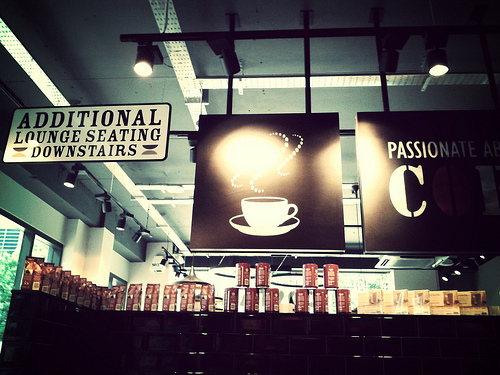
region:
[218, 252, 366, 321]
The cans are stacked.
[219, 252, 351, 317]
The cans are red.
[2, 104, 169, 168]
The sign is white.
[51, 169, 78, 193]
The lights are on.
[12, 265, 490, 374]
The drawers are black.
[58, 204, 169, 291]
The walls are white.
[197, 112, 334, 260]
The logo is coffee cup.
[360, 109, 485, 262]
The sign is black.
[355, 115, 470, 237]
The text is white.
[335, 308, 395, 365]
The handles are silver.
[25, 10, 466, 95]
ceiling of large room with beams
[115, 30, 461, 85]
hanging lights facing downwards and shining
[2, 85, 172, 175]
oblong sign telling customers where to find more seats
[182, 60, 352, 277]
square sign showing a cup of coffee below twisted dots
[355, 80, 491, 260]
dark sign with letter of alphabet and a word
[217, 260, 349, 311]
cans spaced apart and supporting other cans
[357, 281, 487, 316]
packages displayed in a repeated pattern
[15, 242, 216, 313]
packages aligned on ledges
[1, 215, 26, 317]
window showing a tall building and a tree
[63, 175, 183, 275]
rows of lights pointed in different angles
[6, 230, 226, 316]
several pound bags of coffee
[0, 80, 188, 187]
informational sign with the letter a on it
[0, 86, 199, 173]
informational sign with the letter d on it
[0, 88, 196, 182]
informational sign with the letter i on it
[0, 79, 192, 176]
informational sign with the letter o on it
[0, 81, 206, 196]
informational sign with the letter n on it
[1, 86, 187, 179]
informational sign with the letter l on it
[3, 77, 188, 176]
informational sign with the letter u on it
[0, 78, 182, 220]
informational sign with the letter g on it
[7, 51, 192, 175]
informational sign with the letter s on it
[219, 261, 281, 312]
the boxes are stacked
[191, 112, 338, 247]
the poster has a coffee image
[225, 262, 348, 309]
the boxes are red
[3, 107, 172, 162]
sign says, "additional lounge seating downstairs"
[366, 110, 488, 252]
the sign says "C"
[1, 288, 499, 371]
the counter is dark brown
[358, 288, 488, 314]
the boxes are beige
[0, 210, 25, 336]
the trees are seen through the window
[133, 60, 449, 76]
two lights are on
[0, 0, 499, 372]
the image takes place indoors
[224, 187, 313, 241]
image of a coffee cup on banner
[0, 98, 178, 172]
sign in a restaurant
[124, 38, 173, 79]
light fixture illuminated on ceiling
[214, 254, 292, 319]
cans stacked on a ledge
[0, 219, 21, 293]
window to the outdoors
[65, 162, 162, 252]
row of lights on ceiling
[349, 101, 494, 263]
advertising board hanging from ceiling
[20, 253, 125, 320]
bags of coffee on counter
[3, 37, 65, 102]
metal beams on the ceiling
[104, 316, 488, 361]
tile under a shelf